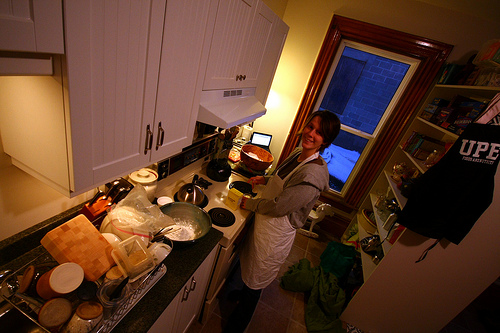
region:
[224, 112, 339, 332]
a woman wearing a white apron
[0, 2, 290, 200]
white wooden cabinets over sink and stove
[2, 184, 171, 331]
dishes in a dish drainer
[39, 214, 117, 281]
a light colored wooden cutting board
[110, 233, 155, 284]
a clear plastic container in drainer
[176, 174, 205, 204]
a silver tea kettle on stove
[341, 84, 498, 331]
white wooden kitchen pantry shelves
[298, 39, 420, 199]
a glass storm door in kitchen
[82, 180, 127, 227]
a wooden knife block with knives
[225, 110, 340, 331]
a girl with short hair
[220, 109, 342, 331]
A woman in an apron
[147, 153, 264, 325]
An electric stove and oven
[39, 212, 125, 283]
A wooden cutting board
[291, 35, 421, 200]
A large kitchen window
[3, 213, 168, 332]
A dring rack filled with dished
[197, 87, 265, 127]
A vent hood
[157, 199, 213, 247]
A mixing bowl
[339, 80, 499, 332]
A set of white pantry shelves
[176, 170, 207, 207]
A tea kettle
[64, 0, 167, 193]
A white kitchen cabinet door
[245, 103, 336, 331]
woman at stove top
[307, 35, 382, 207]
door to the outside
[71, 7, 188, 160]
cabinets on the wall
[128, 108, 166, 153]
handles on the cabinets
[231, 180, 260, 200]
pan on the stove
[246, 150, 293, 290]
apron on the woman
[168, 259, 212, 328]
cabinets near the floor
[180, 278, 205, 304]
handles on the cabinets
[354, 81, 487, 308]
pantry with shelves inside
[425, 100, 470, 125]
items on a shelf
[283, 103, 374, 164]
the head of a woman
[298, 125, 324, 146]
the nose of a woman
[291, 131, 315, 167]
the chin of a woman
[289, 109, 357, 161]
the hair of a woman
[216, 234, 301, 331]
the legs of a woman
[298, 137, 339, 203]
the neck of a woman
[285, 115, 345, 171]
the cheek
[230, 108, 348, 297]
a woman wearing a white apron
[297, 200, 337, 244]
a white wood rocking horse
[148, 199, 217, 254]
large green bowl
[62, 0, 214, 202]
two white cupboard doors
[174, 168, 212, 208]
a silver tea pot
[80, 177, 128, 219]
a wood knife holder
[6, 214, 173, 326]
a dish rack full of clean dishes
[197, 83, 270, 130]
white ventilation fan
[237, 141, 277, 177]
a wood bowl with flour in it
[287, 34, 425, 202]
a window showing outside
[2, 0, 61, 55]
a door for a cabinet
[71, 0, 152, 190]
a door for a cabinet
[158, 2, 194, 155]
a door for a cabinet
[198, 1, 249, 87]
a door for a cabinet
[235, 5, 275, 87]
a door for a cabinet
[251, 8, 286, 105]
a door for a cabinet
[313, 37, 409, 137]
a window on a building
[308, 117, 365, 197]
a window on a building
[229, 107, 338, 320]
a person is standing up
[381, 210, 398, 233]
a bottle for holding liquid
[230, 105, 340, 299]
woman in kitchen wearing apron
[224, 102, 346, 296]
woman in kitchen wearing apron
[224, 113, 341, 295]
woman in kitchen wearing apron